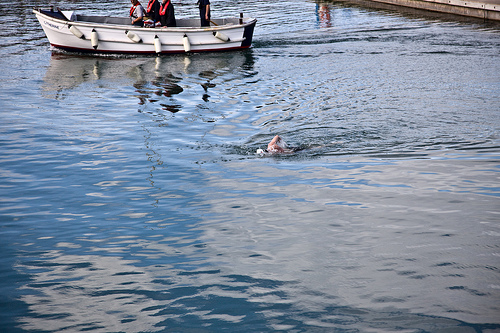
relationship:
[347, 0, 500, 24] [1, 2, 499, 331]
dock on water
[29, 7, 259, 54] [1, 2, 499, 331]
boat on water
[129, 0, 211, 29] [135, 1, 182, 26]
people wearing vest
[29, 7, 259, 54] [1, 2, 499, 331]
boat in water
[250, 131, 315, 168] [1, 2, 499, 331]
man in water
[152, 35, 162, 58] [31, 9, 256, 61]
buoy on boat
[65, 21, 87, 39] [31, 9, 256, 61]
buoy on boat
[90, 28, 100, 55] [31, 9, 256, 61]
buoy on boat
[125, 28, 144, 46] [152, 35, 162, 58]
buoy on buoy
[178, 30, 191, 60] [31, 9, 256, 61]
buoy on boat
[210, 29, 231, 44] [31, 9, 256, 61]
buoy on boat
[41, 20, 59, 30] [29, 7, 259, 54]
writing on boat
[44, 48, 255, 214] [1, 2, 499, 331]
reflection on water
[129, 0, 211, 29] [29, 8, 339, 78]
people in boat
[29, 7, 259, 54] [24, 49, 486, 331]
boat in water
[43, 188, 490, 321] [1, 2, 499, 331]
waves in water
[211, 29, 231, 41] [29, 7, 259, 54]
gunport on boat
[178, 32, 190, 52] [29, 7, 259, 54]
gunport on boat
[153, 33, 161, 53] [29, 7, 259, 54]
gunport on boat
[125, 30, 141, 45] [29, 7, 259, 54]
gunport on boat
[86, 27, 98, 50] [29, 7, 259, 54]
gunport on boat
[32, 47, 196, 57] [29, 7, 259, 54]
wale lower boat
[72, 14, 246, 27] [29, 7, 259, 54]
deck on boat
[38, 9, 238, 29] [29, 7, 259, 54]
deck on boat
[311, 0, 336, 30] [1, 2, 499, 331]
reflection on water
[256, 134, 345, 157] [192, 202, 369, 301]
man inside water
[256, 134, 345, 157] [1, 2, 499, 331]
man inside water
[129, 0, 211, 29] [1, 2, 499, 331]
people inside water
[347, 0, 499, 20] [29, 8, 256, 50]
dock behind boat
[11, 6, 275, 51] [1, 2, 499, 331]
boat on water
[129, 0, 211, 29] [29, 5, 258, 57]
people standing on boat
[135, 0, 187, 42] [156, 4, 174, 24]
people wearing life preserver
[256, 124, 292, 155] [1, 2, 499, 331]
object in water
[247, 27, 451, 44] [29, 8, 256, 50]
trail behind boat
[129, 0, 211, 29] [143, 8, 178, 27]
people wearing clothing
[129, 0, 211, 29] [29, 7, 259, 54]
people in a boat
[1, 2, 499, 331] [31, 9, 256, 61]
water beneath boat